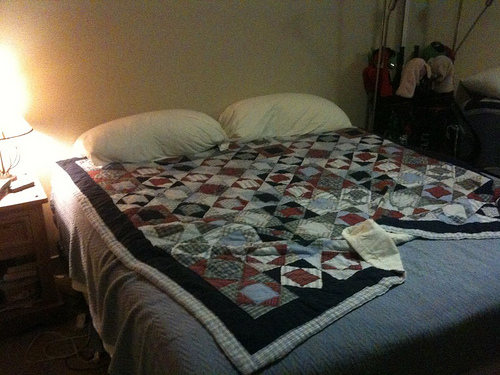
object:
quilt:
[57, 125, 500, 375]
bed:
[48, 127, 500, 375]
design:
[281, 268, 320, 287]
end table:
[0, 175, 64, 325]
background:
[0, 0, 500, 375]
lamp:
[0, 102, 35, 176]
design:
[205, 259, 245, 280]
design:
[116, 193, 156, 206]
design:
[211, 195, 248, 211]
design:
[229, 206, 271, 226]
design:
[340, 212, 367, 226]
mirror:
[402, 0, 500, 178]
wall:
[0, 0, 372, 260]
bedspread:
[49, 166, 500, 375]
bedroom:
[0, 0, 500, 375]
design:
[321, 250, 362, 272]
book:
[8, 176, 34, 193]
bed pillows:
[71, 108, 231, 167]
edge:
[176, 295, 215, 342]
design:
[259, 200, 318, 223]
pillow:
[218, 92, 354, 140]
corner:
[229, 346, 269, 375]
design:
[237, 280, 285, 308]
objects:
[393, 57, 432, 102]